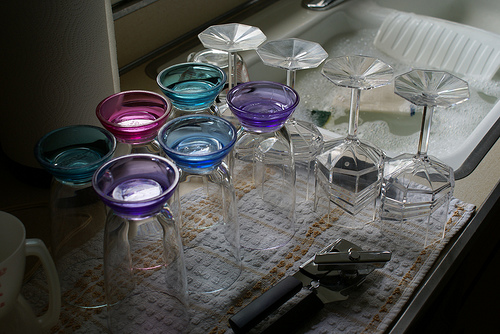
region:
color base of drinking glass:
[86, 141, 196, 331]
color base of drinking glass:
[36, 115, 122, 317]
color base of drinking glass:
[150, 98, 250, 198]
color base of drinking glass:
[91, 74, 181, 148]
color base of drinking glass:
[224, 77, 304, 142]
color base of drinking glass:
[154, 56, 227, 110]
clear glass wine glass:
[201, 17, 261, 105]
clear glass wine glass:
[371, 46, 468, 263]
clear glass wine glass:
[314, 23, 393, 245]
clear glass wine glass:
[256, 21, 333, 235]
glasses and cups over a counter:
[34, 18, 479, 332]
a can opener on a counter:
[217, 225, 393, 331]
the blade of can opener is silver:
[311, 234, 396, 291]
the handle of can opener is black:
[223, 269, 325, 331]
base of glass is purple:
[223, 77, 308, 246]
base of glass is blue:
[159, 110, 249, 296]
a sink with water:
[242, 0, 498, 176]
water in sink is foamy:
[231, 0, 498, 175]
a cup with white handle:
[0, 205, 70, 332]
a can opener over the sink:
[218, 230, 395, 332]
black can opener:
[222, 277, 319, 332]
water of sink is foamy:
[291, 30, 488, 162]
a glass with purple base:
[91, 147, 188, 327]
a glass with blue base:
[165, 110, 248, 291]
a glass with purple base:
[225, 75, 300, 250]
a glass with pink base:
[96, 82, 171, 141]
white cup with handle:
[0, 210, 70, 332]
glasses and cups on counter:
[15, 22, 463, 324]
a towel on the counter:
[25, 111, 474, 332]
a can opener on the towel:
[227, 227, 389, 332]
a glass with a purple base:
[90, 154, 205, 331]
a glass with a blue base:
[165, 114, 245, 290]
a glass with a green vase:
[35, 123, 113, 315]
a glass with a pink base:
[87, 82, 172, 150]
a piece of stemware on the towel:
[378, 66, 452, 244]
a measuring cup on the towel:
[0, 205, 70, 331]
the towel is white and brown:
[18, 102, 479, 331]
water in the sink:
[272, 8, 486, 173]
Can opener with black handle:
[228, 237, 392, 327]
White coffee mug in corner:
[0, 208, 62, 326]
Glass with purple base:
[93, 152, 189, 330]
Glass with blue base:
[158, 114, 240, 291]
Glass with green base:
[36, 123, 103, 304]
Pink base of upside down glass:
[94, 90, 169, 141]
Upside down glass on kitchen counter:
[227, 80, 297, 245]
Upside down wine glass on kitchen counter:
[382, 67, 471, 248]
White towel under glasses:
[23, 122, 474, 332]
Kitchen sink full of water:
[241, 10, 498, 174]